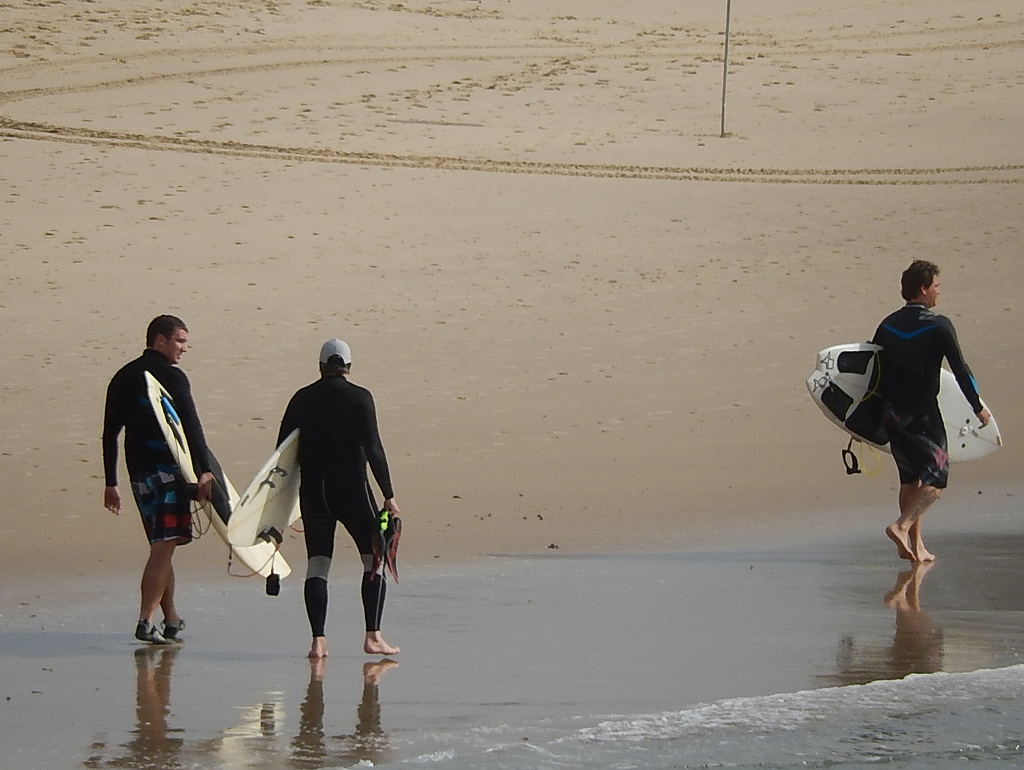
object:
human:
[227, 335, 400, 664]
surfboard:
[225, 415, 307, 569]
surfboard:
[802, 336, 1005, 463]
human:
[99, 312, 291, 645]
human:
[805, 260, 1001, 561]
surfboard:
[135, 365, 286, 582]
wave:
[388, 655, 1018, 759]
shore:
[0, 0, 1024, 765]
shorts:
[130, 471, 193, 543]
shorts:
[886, 404, 952, 493]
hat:
[318, 336, 353, 362]